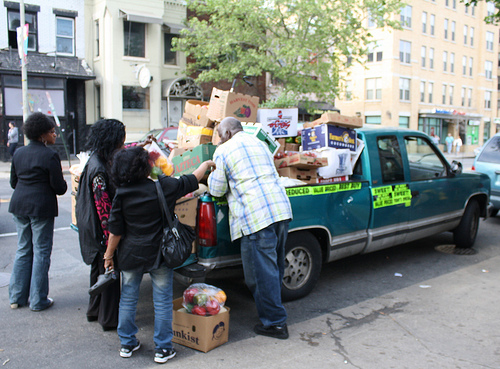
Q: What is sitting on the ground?
A: Cardboard box.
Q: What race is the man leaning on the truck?
A: Black.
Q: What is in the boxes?
A: Fruit.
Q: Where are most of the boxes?
A: In the pickup truck.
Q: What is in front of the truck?
A: Teal minivan.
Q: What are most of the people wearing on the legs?
A: Jeans.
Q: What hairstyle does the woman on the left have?
A: Afro.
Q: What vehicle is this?
A: A pickup truck.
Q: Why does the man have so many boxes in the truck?
A: He is selling food.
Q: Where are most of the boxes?
A: Bed of the truck.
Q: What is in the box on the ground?
A: Food.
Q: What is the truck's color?
A: Green.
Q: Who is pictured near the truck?
A: Four people.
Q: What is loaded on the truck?
A: Boxes of produce.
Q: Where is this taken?
A: A city street.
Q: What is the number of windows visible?
A: At least 29.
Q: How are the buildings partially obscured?
A: By a tree.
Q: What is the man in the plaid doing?
A: Selling produce.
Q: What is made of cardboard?
A: Boxes.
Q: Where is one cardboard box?
A: On the ground.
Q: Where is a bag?
A: Over woman's shoulder.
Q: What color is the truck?
A: Green.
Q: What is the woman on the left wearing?
A: A black coat and jeans.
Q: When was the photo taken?
A: Daytime.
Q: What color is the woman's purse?
A: Black.